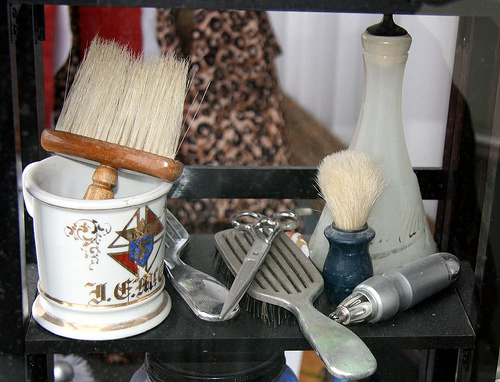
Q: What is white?
A: Brush.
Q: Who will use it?
A: People.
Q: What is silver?
A: The scissors.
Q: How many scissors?
A: 1.